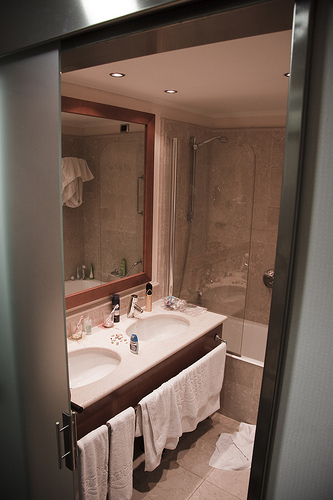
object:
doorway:
[82, 118, 264, 499]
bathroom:
[0, 5, 332, 497]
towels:
[137, 341, 226, 474]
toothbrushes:
[170, 269, 178, 309]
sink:
[126, 312, 195, 345]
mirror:
[62, 113, 144, 295]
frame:
[142, 116, 158, 284]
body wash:
[120, 259, 126, 276]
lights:
[162, 83, 178, 96]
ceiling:
[56, 38, 294, 126]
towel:
[63, 155, 92, 208]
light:
[105, 70, 128, 79]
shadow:
[139, 426, 217, 489]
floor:
[126, 406, 256, 500]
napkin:
[200, 430, 231, 473]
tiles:
[159, 446, 227, 497]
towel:
[108, 405, 136, 499]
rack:
[78, 407, 153, 432]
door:
[0, 51, 77, 500]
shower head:
[192, 134, 230, 146]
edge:
[59, 94, 164, 123]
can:
[146, 282, 153, 312]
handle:
[258, 266, 280, 295]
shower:
[174, 130, 263, 357]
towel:
[210, 421, 255, 472]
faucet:
[126, 300, 145, 316]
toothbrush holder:
[70, 318, 86, 339]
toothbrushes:
[76, 312, 88, 329]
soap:
[174, 295, 190, 312]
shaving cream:
[112, 286, 120, 320]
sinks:
[66, 346, 120, 388]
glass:
[100, 306, 116, 329]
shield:
[158, 107, 286, 306]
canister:
[102, 293, 122, 324]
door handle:
[54, 410, 81, 474]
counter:
[66, 295, 229, 410]